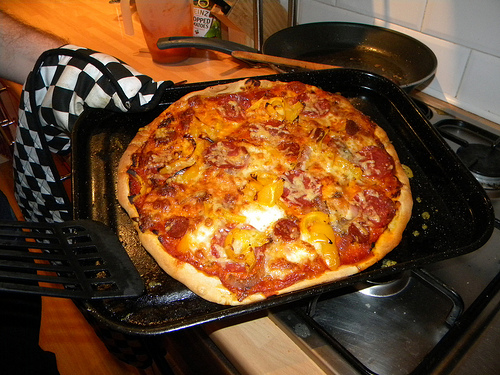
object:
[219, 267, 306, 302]
tomato sauce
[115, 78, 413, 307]
pizza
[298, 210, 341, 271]
peppers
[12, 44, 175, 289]
oven mitt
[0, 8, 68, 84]
arm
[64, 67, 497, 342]
pan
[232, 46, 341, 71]
utensil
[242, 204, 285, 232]
cheese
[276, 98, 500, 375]
oven top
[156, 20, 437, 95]
frying pan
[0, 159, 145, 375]
floor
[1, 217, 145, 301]
spatula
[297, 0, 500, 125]
wall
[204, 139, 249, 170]
pepperoni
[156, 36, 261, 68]
handle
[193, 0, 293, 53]
knife block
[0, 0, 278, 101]
counter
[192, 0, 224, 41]
bottle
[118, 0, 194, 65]
pitcher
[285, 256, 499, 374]
burner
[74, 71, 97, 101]
square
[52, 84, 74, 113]
square